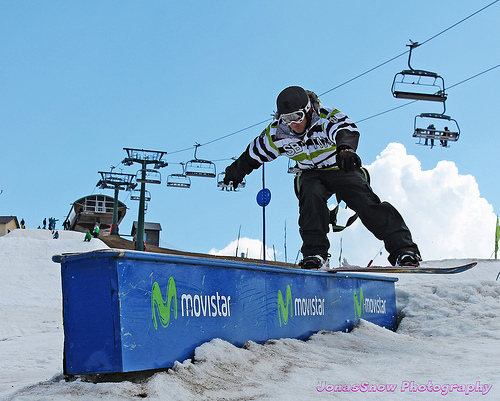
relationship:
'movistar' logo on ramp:
[179, 288, 236, 322] [52, 244, 404, 377]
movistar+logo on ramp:
[142, 269, 236, 336] [52, 244, 404, 377]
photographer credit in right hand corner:
[310, 373, 493, 397] [309, 371, 499, 399]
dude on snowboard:
[202, 73, 481, 278] [319, 258, 481, 280]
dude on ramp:
[202, 73, 481, 278] [52, 244, 404, 377]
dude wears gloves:
[202, 73, 481, 278] [218, 148, 363, 194]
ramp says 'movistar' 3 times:
[52, 244, 404, 377] [136, 275, 387, 335]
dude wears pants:
[202, 73, 481, 278] [293, 168, 424, 260]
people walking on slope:
[17, 210, 104, 246] [0, 229, 113, 401]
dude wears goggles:
[202, 73, 481, 278] [274, 97, 314, 131]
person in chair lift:
[438, 124, 452, 150] [405, 85, 476, 153]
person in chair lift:
[417, 124, 436, 150] [405, 85, 476, 153]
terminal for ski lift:
[62, 188, 135, 241] [52, 1, 499, 234]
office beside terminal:
[125, 212, 163, 250] [62, 188, 135, 241]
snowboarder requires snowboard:
[220, 83, 428, 264] [319, 258, 481, 280]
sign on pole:
[254, 183, 276, 209] [263, 152, 267, 263]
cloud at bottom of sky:
[318, 136, 498, 260] [194, 109, 497, 267]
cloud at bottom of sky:
[208, 230, 284, 265] [194, 109, 497, 267]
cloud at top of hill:
[318, 136, 498, 260] [1, 231, 500, 401]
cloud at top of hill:
[208, 230, 284, 265] [1, 231, 500, 401]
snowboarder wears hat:
[220, 83, 428, 264] [270, 77, 313, 117]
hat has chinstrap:
[270, 77, 313, 117] [290, 105, 313, 138]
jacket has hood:
[243, 105, 369, 172] [299, 87, 324, 117]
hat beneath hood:
[270, 77, 313, 117] [299, 87, 324, 117]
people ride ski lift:
[415, 121, 461, 147] [52, 1, 499, 234]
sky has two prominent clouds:
[2, 1, 499, 256] [201, 113, 498, 263]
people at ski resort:
[17, 210, 104, 246] [0, 178, 206, 273]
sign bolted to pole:
[254, 183, 276, 209] [263, 152, 267, 263]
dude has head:
[202, 73, 481, 278] [272, 82, 317, 142]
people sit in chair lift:
[415, 121, 461, 147] [405, 85, 476, 153]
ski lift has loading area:
[52, 1, 499, 234] [15, 207, 113, 242]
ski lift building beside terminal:
[2, 209, 21, 240] [62, 188, 135, 241]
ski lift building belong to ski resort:
[0, 209, 22, 240] [0, 178, 206, 273]